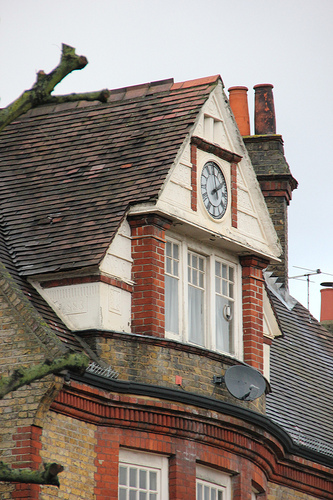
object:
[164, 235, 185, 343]
window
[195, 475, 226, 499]
window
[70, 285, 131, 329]
wall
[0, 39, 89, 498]
tree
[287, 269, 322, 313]
antenna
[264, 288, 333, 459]
roof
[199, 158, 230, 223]
clock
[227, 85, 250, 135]
cones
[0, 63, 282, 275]
top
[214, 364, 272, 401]
dish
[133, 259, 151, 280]
brick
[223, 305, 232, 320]
object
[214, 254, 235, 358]
window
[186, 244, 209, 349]
windows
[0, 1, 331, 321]
sky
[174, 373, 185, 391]
discoloration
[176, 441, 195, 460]
brick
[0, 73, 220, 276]
roof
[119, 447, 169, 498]
white window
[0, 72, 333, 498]
house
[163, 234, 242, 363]
set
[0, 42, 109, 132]
branch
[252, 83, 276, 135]
chimney